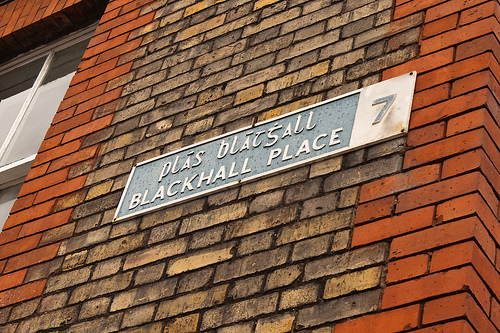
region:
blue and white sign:
[112, 65, 422, 216]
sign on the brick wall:
[112, 60, 416, 226]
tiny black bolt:
[406, 66, 416, 79]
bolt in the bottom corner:
[398, 125, 405, 134]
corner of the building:
[458, 0, 496, 330]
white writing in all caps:
[129, 128, 346, 206]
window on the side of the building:
[1, 0, 111, 297]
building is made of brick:
[1, 0, 493, 331]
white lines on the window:
[2, 30, 86, 251]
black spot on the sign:
[379, 113, 402, 137]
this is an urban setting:
[16, 35, 445, 328]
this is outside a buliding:
[47, 45, 394, 286]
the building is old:
[86, 247, 401, 300]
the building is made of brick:
[52, 225, 369, 332]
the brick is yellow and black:
[81, 235, 309, 329]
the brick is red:
[393, 208, 496, 323]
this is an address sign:
[117, 110, 394, 202]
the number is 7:
[333, 72, 438, 138]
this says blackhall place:
[105, 125, 372, 225]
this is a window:
[9, 56, 111, 173]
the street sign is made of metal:
[114, 70, 416, 227]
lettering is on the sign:
[126, 114, 343, 203]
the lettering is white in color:
[132, 109, 347, 214]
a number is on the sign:
[367, 88, 398, 128]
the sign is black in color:
[370, 93, 393, 123]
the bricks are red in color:
[355, 2, 495, 327]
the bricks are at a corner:
[380, 3, 497, 327]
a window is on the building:
[0, 8, 89, 252]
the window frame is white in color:
[0, 30, 99, 258]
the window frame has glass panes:
[3, 35, 93, 254]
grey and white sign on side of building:
[111, 62, 422, 228]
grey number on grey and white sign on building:
[357, 87, 399, 134]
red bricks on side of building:
[384, 188, 476, 235]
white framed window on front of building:
[2, 6, 110, 261]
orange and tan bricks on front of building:
[168, 31, 300, 98]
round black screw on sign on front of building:
[404, 68, 420, 82]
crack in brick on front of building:
[281, 265, 316, 288]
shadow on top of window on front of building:
[3, 24, 103, 101]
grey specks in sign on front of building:
[325, 106, 351, 121]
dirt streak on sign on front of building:
[374, 104, 403, 139]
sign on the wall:
[111, 65, 423, 227]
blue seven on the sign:
[368, 90, 395, 125]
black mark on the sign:
[380, 110, 402, 134]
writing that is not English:
[143, 101, 321, 179]